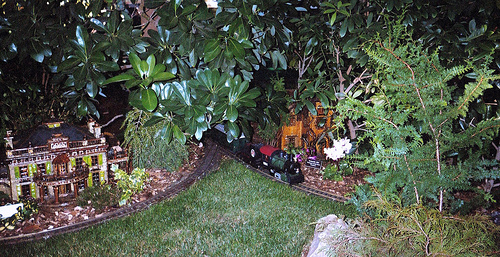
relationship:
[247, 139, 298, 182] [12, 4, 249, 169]
train car under tree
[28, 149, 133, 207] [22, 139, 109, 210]
balcony above entrance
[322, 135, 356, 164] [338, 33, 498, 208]
white flower on bush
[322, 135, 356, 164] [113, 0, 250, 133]
white flower on bush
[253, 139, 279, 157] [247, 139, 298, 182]
red top on train car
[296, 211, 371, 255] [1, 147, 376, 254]
rock on grass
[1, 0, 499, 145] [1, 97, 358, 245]
tree above train set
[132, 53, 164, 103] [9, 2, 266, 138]
leaves are on tree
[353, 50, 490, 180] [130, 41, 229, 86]
tree with leaves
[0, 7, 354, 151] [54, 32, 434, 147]
tree has branches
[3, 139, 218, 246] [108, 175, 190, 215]
track has no train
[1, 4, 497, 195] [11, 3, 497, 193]
leaves are on trees